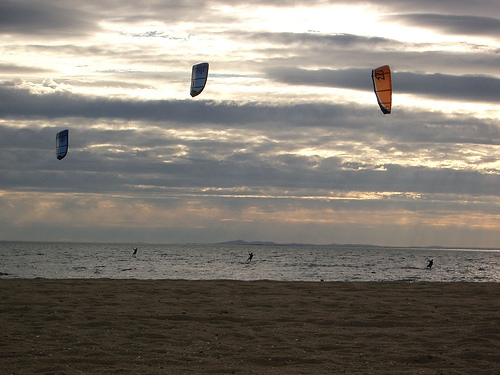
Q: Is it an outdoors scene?
A: Yes, it is outdoors.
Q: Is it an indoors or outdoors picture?
A: It is outdoors.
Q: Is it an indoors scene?
A: No, it is outdoors.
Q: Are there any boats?
A: No, there are no boats.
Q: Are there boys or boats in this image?
A: No, there are no boats or boys.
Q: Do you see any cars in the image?
A: No, there are no cars.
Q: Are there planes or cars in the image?
A: No, there are no cars or planes.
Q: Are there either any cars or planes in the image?
A: No, there are no cars or planes.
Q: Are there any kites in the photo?
A: Yes, there is a kite.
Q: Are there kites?
A: Yes, there is a kite.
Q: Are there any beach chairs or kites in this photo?
A: Yes, there is a kite.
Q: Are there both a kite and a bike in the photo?
A: No, there is a kite but no bikes.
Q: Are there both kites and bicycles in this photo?
A: No, there is a kite but no bikes.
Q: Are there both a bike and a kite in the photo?
A: No, there is a kite but no bikes.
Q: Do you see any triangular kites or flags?
A: Yes, there is a triangular kite.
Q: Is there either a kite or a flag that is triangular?
A: Yes, the kite is triangular.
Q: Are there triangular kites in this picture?
A: Yes, there is a triangular kite.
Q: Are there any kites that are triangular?
A: Yes, there is a kite that is triangular.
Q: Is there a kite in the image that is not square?
A: Yes, there is a triangular kite.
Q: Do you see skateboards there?
A: No, there are no skateboards.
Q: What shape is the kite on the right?
A: The kite is triangular.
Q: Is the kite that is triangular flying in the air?
A: Yes, the kite is flying in the air.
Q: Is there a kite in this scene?
A: Yes, there is a kite.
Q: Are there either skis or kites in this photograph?
A: Yes, there is a kite.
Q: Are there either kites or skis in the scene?
A: Yes, there is a kite.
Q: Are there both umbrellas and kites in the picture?
A: No, there is a kite but no umbrellas.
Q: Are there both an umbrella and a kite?
A: No, there is a kite but no umbrellas.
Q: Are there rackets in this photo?
A: No, there are no rackets.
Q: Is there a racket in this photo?
A: No, there are no rackets.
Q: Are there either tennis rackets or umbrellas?
A: No, there are no tennis rackets or umbrellas.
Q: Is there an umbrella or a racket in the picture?
A: No, there are no rackets or umbrellas.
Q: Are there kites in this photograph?
A: Yes, there is a kite.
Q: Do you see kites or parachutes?
A: Yes, there is a kite.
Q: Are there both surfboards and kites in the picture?
A: No, there is a kite but no surfboards.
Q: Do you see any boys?
A: No, there are no boys.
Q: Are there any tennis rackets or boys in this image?
A: No, there are no boys or tennis rackets.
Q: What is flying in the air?
A: The kite is flying in the air.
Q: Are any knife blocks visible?
A: No, there are no knife blocks.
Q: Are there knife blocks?
A: No, there are no knife blocks.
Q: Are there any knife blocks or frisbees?
A: No, there are no knife blocks or frisbees.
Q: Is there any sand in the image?
A: Yes, there is sand.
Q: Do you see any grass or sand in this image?
A: Yes, there is sand.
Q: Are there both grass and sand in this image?
A: No, there is sand but no grass.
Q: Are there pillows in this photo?
A: No, there are no pillows.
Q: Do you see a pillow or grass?
A: No, there are no pillows or grass.